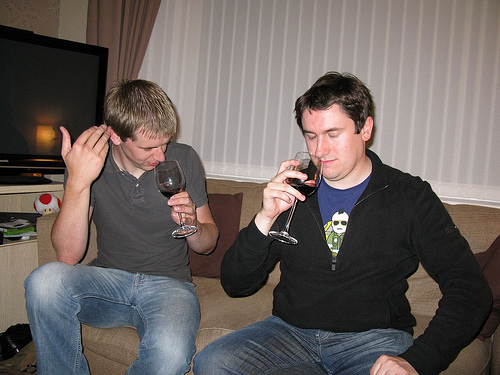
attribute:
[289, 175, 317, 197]
wine — red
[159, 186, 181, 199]
wine — red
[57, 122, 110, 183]
hand — up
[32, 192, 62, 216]
mushroom — stuffed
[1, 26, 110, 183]
television — black, big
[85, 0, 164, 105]
curtain — brown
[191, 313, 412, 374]
jeans — blue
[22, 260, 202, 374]
jeans — blue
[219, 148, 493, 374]
fleece — black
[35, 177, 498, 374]
couch — brown, light brown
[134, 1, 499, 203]
blinds — white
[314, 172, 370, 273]
shirt — blue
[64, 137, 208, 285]
shirt — grey